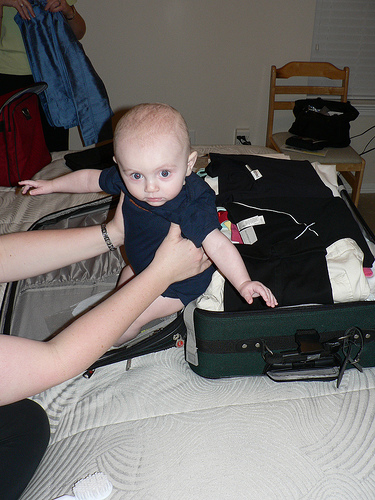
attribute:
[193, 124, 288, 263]
suitcase — green 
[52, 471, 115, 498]
brush — white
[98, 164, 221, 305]
shirt — blue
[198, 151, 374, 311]
clothes — folded